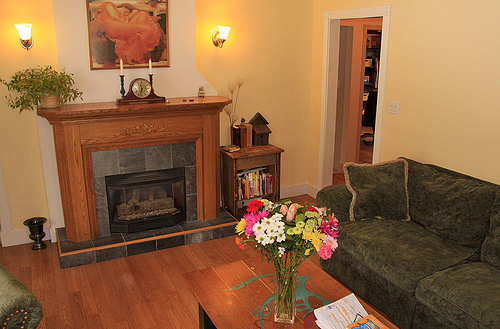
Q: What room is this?
A: Living room.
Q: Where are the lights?
A: On the wall.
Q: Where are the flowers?
A: On the table.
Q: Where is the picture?
A: Above the fireplace.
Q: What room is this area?
A: Living room.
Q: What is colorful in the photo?
A: The flowers.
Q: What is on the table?
A: The vase.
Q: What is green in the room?
A: The couch.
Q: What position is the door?
A: Open.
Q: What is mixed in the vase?
A: Flowers.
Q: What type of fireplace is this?
A: Electric.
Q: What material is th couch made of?
A: Cloth.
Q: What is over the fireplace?
A: A painting.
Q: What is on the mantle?
A: A clock.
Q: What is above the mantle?
A: A painting.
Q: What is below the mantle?
A: A fireplace.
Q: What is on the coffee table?
A: A vase.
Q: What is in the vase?
A: Flowers.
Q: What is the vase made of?
A: Glass.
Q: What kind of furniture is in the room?
A: Upholstered.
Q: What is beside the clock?
A: Candles.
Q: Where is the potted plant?
A: On the mantle.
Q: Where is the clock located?
A: On the fireplace mantel.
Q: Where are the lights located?
A: On the far wall on each side of the fireplace.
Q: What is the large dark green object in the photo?
A: A couch.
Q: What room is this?
A: Living room.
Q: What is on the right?
A: Green couch.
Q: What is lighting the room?
A: Lights.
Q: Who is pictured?
A: No one.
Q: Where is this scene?
A: Inside a house.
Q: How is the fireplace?
A: Unlit.